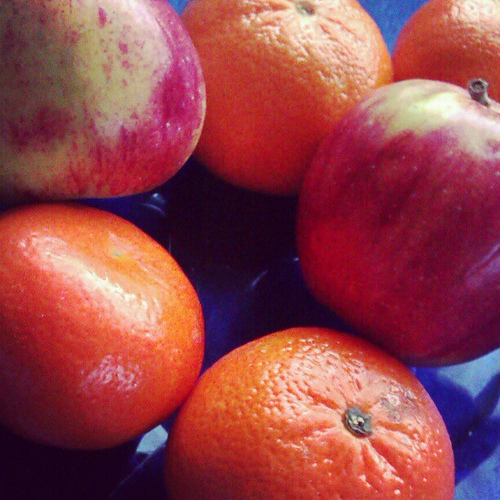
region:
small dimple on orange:
[280, 387, 319, 422]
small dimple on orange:
[239, 364, 281, 396]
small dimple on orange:
[280, 346, 334, 385]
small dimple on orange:
[317, 351, 357, 369]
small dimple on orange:
[257, 337, 300, 367]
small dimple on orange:
[341, 356, 389, 398]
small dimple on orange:
[402, 428, 433, 456]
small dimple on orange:
[255, 439, 323, 467]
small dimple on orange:
[205, 423, 271, 452]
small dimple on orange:
[361, 449, 418, 479]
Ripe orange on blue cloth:
[180, 334, 455, 499]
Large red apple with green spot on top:
[303, 66, 498, 361]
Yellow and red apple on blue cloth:
[0, 0, 206, 195]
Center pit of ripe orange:
[345, 412, 372, 432]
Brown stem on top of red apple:
[468, 80, 493, 111]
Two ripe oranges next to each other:
[1, 203, 459, 498]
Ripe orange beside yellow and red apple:
[0, 0, 389, 195]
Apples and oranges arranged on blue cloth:
[3, 0, 498, 499]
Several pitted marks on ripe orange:
[231, 348, 341, 416]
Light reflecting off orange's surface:
[31, 237, 165, 336]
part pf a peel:
[298, 365, 347, 435]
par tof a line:
[275, 430, 300, 470]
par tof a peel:
[240, 410, 292, 470]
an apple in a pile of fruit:
[310, 76, 496, 306]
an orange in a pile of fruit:
[189, 338, 435, 498]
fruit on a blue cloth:
[101, 213, 331, 465]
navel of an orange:
[340, 403, 375, 441]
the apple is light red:
[325, 83, 494, 292]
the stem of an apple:
[464, 66, 494, 95]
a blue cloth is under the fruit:
[148, 190, 285, 333]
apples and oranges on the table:
[1, 57, 480, 471]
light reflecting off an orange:
[45, 218, 129, 310]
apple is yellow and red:
[41, 64, 176, 141]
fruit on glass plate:
[1, 1, 498, 498]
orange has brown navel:
[343, 408, 370, 435]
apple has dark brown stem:
[467, 78, 492, 110]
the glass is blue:
[0, 0, 498, 497]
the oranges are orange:
[0, 0, 499, 499]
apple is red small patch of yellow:
[296, 79, 499, 368]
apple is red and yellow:
[2, 0, 202, 201]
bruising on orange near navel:
[383, 380, 424, 428]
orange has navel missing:
[292, 0, 315, 20]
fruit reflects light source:
[0, 0, 499, 497]